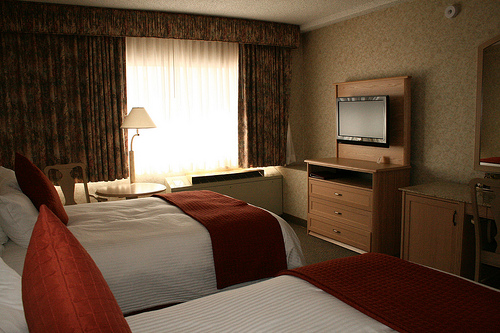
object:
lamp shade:
[121, 106, 158, 129]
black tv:
[334, 94, 393, 148]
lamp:
[120, 106, 157, 183]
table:
[95, 182, 166, 196]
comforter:
[0, 197, 306, 316]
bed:
[0, 161, 305, 315]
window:
[121, 33, 244, 180]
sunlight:
[128, 61, 238, 177]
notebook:
[308, 173, 331, 180]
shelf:
[307, 164, 374, 189]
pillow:
[0, 167, 40, 250]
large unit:
[163, 166, 285, 193]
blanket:
[148, 189, 289, 289]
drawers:
[300, 171, 381, 252]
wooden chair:
[43, 161, 108, 205]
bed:
[4, 252, 499, 332]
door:
[400, 190, 461, 275]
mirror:
[473, 33, 499, 175]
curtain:
[0, 0, 301, 186]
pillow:
[20, 203, 132, 332]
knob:
[333, 190, 339, 196]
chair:
[468, 178, 500, 283]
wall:
[289, 1, 496, 188]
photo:
[0, 0, 499, 332]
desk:
[397, 182, 499, 278]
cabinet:
[303, 157, 414, 254]